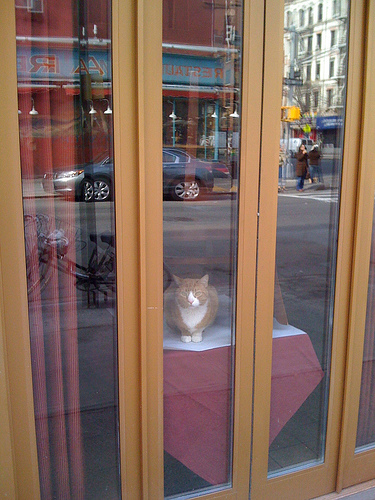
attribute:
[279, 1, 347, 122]
building — apartment building, white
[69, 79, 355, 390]
window — double, glass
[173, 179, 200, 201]
rim — silver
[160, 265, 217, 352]
cat — orange, white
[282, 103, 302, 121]
sign — small, yellow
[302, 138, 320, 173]
person — standing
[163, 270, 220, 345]
cat — white, orange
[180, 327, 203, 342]
legs — white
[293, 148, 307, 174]
jacket — brown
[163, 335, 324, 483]
table cloth — red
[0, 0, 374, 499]
frame — wooden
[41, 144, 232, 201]
car — gray